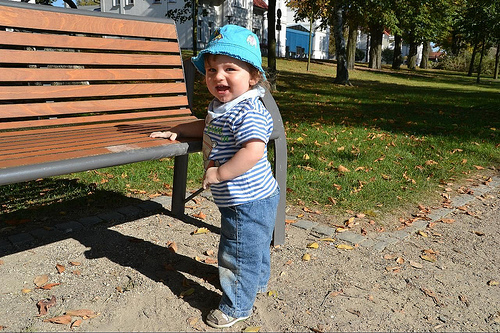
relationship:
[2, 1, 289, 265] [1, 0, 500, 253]
bench in park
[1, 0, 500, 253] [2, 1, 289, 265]
park has bench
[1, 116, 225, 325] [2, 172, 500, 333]
shadow on sidewalk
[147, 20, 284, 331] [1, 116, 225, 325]
child has shadow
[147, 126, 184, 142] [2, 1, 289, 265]
hand on bench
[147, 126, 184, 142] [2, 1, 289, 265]
hand resting on bench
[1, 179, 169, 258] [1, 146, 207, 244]
shadow on grass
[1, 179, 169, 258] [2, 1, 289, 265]
shadow of bench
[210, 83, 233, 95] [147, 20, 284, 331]
smile on boy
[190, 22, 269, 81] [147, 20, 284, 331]
hat on kid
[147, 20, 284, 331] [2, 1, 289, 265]
toddler by bench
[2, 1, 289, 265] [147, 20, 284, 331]
bench by toddler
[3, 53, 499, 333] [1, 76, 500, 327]
ground has leaves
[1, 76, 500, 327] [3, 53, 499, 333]
leaves on ground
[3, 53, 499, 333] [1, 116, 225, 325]
ground has shadow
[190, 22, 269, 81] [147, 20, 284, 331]
hat on boy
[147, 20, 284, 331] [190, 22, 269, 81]
boy has hat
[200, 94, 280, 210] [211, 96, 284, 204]
shirt has stripes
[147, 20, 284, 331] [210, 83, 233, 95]
child has smile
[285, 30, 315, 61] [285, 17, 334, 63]
blue door on building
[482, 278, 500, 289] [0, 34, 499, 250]
leaves in grass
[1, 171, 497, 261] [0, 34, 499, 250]
bricks surrounding grass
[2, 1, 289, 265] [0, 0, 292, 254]
bench has metal trim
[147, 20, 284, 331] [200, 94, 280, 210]
girl has shirt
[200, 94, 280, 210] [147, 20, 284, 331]
shirt on girl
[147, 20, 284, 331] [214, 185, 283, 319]
child wearing jeans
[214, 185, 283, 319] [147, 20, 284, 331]
jeans on child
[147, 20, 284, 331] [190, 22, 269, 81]
child has hat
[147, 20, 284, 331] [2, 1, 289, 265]
child near bench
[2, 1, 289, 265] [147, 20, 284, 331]
bench near child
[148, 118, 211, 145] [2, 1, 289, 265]
right arm on bench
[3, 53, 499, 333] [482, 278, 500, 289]
ground has leaves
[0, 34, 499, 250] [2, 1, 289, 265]
grass near bench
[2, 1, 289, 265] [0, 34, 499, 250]
bench near grass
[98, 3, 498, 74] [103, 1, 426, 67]
background has buildings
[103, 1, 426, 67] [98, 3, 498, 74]
buildings in background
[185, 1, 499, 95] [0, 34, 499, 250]
trees in grass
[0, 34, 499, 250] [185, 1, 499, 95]
grass has trees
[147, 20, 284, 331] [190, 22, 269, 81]
child wearing hat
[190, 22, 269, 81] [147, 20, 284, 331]
hat on child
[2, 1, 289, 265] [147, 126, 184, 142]
bench with hand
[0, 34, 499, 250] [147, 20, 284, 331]
grass behind child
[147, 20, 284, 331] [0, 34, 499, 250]
child by grass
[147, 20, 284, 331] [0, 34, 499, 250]
child near grass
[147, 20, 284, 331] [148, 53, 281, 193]
child has skin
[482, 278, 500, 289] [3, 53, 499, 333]
leaves on ground